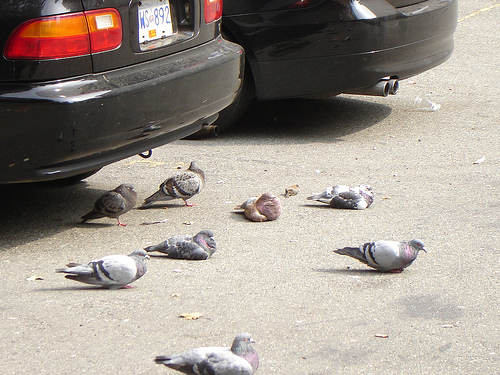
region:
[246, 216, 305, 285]
[part of a road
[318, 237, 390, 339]
[part of a shade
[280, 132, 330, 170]
edge of a shade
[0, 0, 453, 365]
several pigeons lying under cars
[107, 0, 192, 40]
the back licence plate of a car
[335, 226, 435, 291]
a pigeon lying on the street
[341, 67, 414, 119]
the twin mufflers on a black car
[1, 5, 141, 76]
the brake and tail light on a car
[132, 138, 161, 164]
the tow hitch on the back of a car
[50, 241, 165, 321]
a pigeon with two stripes on his wing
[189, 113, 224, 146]
the tail pipe on a car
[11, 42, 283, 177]
the bumper of a car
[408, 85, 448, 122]
a discarded plastic cup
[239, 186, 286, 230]
brown bird laying on the pavement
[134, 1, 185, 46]
blue and white license plate on back of car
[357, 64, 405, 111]
dual exhaust pipes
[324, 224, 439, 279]
pigeon sitting on the ground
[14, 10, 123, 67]
red and yellow lights on the bumper of the car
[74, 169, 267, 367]
lots of birds on the pavement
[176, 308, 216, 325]
leaf on the pavement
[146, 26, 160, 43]
yellow sticker on license plate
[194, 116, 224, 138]
small exhaust pipe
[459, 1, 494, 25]
crack in the pavement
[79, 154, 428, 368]
eight pigeons in a parking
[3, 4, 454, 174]
a couple of black cars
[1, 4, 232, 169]
rear view of the left black car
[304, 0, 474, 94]
rear view of the right black car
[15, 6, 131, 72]
left signal light of the left black car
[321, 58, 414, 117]
the muffler of the right black car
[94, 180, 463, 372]
eight pigeons in different positions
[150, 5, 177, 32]
the number 892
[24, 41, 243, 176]
the rear bumper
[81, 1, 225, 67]
the closed trunk car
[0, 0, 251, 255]
black car parked in parking lot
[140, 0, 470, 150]
black car parked in parking lot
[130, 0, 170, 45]
white license plate with blue letters and numbers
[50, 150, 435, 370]
group of eight pigeons sitting on concrete parking lot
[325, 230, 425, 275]
gray and white pigeon sitting on concrete parking lot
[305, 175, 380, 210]
gray and white pigeon sitting on concrete parking lot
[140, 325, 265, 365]
gray and white pigeon sitting on concrete parking lot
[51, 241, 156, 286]
gray and white pigeon sitting on concrete parking lot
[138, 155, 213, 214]
gray and white pigeon standing on concrete parking lot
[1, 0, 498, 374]
light gray concrete parking lot